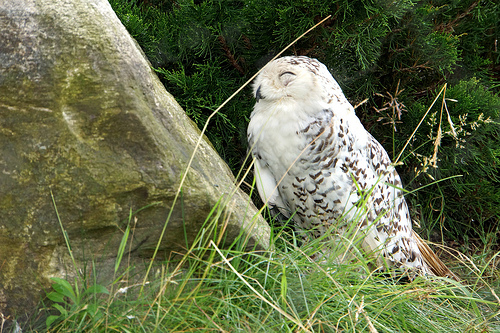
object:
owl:
[245, 54, 445, 289]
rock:
[0, 0, 276, 332]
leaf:
[46, 275, 77, 301]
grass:
[257, 246, 316, 293]